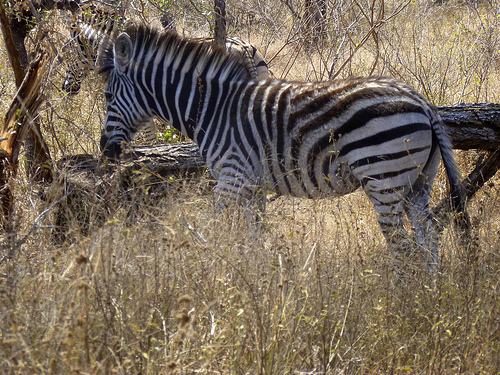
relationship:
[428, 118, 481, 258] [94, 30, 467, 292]
tail on zebra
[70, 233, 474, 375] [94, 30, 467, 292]
grass next to zebra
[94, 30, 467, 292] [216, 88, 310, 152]
zebra has stripes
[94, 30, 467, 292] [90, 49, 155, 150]
zebra has head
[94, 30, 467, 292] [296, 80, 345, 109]
zebra has hair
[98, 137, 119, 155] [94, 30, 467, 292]
nose of a zebra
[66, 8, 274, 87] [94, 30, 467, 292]
zebra behind zebra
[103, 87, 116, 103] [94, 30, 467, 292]
eye of zebra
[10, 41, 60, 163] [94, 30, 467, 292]
branch by zebra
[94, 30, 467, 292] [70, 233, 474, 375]
zebra in grass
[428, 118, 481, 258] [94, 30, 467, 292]
tail of zebra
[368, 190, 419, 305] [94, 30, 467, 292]
leg of zebra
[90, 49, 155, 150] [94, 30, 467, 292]
head of zebra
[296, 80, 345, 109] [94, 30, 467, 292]
hair on back of zebra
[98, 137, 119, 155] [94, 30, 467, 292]
nose of zebra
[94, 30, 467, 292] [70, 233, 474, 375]
zebra standing in grass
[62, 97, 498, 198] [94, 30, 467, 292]
log in front of zebra